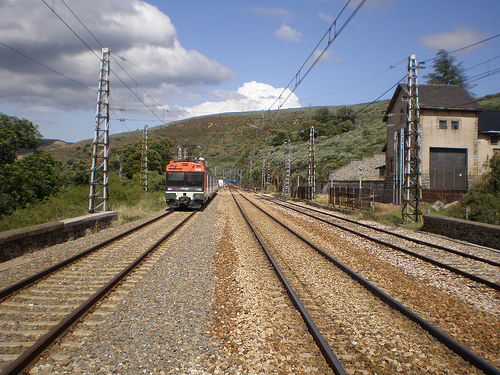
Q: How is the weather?
A: It is cloudy.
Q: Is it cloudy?
A: Yes, it is cloudy.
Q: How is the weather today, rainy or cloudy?
A: It is cloudy.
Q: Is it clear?
A: No, it is cloudy.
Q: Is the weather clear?
A: No, it is cloudy.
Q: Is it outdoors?
A: Yes, it is outdoors.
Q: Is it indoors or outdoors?
A: It is outdoors.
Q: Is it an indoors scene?
A: No, it is outdoors.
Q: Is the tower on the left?
A: Yes, the tower is on the left of the image.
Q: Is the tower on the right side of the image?
A: No, the tower is on the left of the image.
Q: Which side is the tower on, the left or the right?
A: The tower is on the left of the image.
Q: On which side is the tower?
A: The tower is on the left of the image.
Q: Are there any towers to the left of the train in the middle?
A: Yes, there is a tower to the left of the train.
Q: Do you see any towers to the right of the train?
A: No, the tower is to the left of the train.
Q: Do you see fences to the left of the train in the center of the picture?
A: No, there is a tower to the left of the train.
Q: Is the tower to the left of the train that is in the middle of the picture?
A: Yes, the tower is to the left of the train.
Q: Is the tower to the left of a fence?
A: No, the tower is to the left of the train.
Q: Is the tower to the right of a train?
A: No, the tower is to the left of a train.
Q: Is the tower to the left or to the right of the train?
A: The tower is to the left of the train.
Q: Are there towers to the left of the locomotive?
A: Yes, there is a tower to the left of the locomotive.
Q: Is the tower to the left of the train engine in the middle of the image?
A: Yes, the tower is to the left of the engine.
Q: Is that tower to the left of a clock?
A: No, the tower is to the left of the engine.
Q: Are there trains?
A: Yes, there is a train.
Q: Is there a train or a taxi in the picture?
A: Yes, there is a train.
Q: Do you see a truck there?
A: No, there are no trucks.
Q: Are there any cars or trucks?
A: No, there are no trucks or cars.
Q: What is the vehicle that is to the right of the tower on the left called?
A: The vehicle is a train.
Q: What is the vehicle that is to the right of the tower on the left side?
A: The vehicle is a train.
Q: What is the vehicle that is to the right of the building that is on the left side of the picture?
A: The vehicle is a train.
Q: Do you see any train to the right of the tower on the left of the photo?
A: Yes, there is a train to the right of the tower.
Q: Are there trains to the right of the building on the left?
A: Yes, there is a train to the right of the tower.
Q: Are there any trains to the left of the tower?
A: No, the train is to the right of the tower.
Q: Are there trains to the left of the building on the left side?
A: No, the train is to the right of the tower.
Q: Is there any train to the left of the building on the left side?
A: No, the train is to the right of the tower.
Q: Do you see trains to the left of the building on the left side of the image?
A: No, the train is to the right of the tower.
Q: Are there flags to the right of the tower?
A: No, there is a train to the right of the tower.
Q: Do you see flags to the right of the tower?
A: No, there is a train to the right of the tower.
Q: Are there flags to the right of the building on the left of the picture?
A: No, there is a train to the right of the tower.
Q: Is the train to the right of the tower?
A: Yes, the train is to the right of the tower.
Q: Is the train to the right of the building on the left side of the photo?
A: Yes, the train is to the right of the tower.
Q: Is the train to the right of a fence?
A: No, the train is to the right of the tower.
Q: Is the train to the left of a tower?
A: No, the train is to the right of a tower.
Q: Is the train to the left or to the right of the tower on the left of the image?
A: The train is to the right of the tower.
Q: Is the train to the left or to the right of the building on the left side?
A: The train is to the right of the tower.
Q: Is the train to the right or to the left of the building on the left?
A: The train is to the right of the tower.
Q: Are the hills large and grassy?
A: Yes, the hills are large and grassy.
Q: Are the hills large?
A: Yes, the hills are large.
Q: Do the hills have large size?
A: Yes, the hills are large.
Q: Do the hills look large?
A: Yes, the hills are large.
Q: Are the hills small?
A: No, the hills are large.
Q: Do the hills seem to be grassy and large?
A: Yes, the hills are grassy and large.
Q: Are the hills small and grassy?
A: No, the hills are grassy but large.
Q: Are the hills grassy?
A: Yes, the hills are grassy.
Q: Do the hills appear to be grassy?
A: Yes, the hills are grassy.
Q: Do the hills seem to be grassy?
A: Yes, the hills are grassy.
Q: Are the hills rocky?
A: No, the hills are grassy.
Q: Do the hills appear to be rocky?
A: No, the hills are grassy.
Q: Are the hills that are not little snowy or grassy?
A: The hills are grassy.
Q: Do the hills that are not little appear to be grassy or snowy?
A: The hills are grassy.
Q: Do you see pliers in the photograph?
A: No, there are no pliers.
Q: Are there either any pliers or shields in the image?
A: No, there are no pliers or shields.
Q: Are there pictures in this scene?
A: No, there are no pictures.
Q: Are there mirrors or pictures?
A: No, there are no pictures or mirrors.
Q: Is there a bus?
A: No, there are no buses.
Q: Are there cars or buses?
A: No, there are no buses or cars.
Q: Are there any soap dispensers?
A: No, there are no soap dispensers.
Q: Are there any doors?
A: Yes, there is a door.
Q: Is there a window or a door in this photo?
A: Yes, there is a door.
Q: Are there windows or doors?
A: Yes, there is a door.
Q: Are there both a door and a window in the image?
A: Yes, there are both a door and a window.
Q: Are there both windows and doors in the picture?
A: Yes, there are both a door and a window.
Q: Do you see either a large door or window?
A: Yes, there is a large door.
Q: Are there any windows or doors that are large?
A: Yes, the door is large.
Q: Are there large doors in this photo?
A: Yes, there is a large door.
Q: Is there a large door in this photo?
A: Yes, there is a large door.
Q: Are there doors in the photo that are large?
A: Yes, there is a door that is large.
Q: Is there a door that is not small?
A: Yes, there is a large door.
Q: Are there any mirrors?
A: No, there are no mirrors.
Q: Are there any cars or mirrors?
A: No, there are no mirrors or cars.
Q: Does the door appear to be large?
A: Yes, the door is large.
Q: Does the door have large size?
A: Yes, the door is large.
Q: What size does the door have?
A: The door has large size.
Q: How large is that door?
A: The door is large.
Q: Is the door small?
A: No, the door is large.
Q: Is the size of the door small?
A: No, the door is large.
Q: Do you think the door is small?
A: No, the door is large.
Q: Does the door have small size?
A: No, the door is large.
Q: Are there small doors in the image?
A: No, there is a door but it is large.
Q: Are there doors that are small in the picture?
A: No, there is a door but it is large.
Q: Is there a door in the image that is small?
A: No, there is a door but it is large.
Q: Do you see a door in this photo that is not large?
A: No, there is a door but it is large.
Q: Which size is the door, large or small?
A: The door is large.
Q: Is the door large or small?
A: The door is large.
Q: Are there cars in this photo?
A: No, there are no cars.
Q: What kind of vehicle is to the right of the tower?
A: The vehicle is a locomotive.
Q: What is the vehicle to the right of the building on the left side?
A: The vehicle is a locomotive.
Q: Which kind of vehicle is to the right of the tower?
A: The vehicle is a locomotive.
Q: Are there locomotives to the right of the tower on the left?
A: Yes, there is a locomotive to the right of the tower.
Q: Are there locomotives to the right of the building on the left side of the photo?
A: Yes, there is a locomotive to the right of the tower.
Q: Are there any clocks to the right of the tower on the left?
A: No, there is a locomotive to the right of the tower.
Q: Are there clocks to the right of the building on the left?
A: No, there is a locomotive to the right of the tower.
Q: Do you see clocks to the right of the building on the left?
A: No, there is a locomotive to the right of the tower.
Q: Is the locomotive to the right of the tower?
A: Yes, the locomotive is to the right of the tower.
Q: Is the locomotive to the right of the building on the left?
A: Yes, the locomotive is to the right of the tower.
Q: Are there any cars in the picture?
A: No, there are no cars.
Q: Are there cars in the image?
A: No, there are no cars.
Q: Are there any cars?
A: No, there are no cars.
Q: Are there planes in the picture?
A: No, there are no planes.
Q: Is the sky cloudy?
A: Yes, the sky is cloudy.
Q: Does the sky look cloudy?
A: Yes, the sky is cloudy.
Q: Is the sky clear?
A: No, the sky is cloudy.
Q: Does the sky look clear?
A: No, the sky is cloudy.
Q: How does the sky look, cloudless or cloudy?
A: The sky is cloudy.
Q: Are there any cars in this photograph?
A: No, there are no cars.